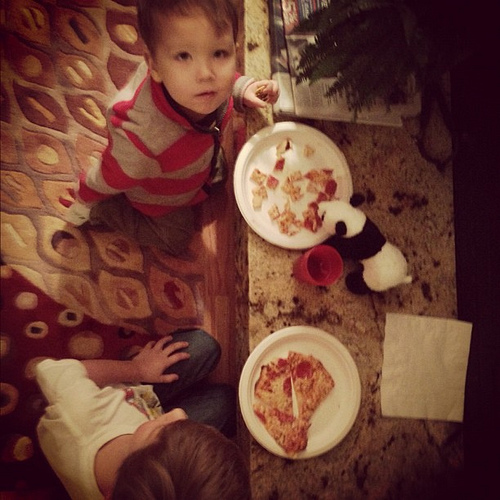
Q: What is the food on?
A: Plates.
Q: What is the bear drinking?
A: Milk.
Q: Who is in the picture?
A: Boys.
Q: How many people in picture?
A: Two.